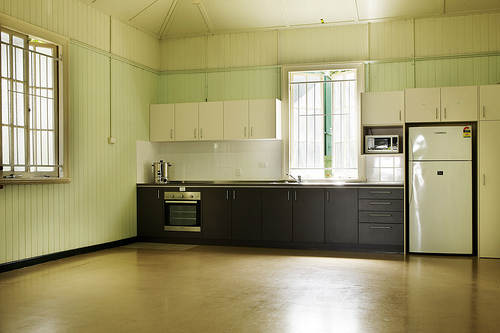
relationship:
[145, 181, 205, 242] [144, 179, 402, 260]
oven built into shelves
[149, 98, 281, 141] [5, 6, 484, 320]
cabinets in kitchen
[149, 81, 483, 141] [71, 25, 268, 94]
cabinets hanging wall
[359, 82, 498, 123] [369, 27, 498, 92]
cabinets hanging on wall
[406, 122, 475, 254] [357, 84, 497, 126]
fridge below cabinets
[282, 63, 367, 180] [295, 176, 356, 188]
window above sink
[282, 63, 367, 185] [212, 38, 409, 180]
window on wall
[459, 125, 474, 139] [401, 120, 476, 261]
magnet on refrigerator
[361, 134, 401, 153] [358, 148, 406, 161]
appliance on shelf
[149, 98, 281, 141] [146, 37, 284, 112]
cabinets are on wall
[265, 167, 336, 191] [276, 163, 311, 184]
sink has faucet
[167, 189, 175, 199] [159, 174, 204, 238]
knob on stove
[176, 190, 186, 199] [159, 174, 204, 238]
knob on stove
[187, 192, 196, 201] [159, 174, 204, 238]
knob on stove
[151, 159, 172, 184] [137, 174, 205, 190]
appliance on counter